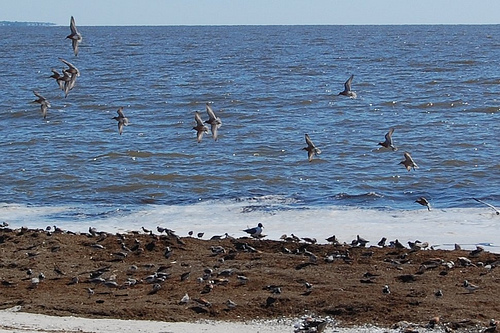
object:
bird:
[396, 151, 419, 172]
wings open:
[417, 196, 429, 204]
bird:
[376, 127, 398, 152]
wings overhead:
[384, 128, 395, 145]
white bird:
[140, 226, 150, 233]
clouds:
[0, 0, 500, 27]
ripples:
[0, 150, 292, 194]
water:
[1, 23, 500, 255]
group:
[25, 17, 432, 213]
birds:
[26, 15, 419, 172]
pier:
[0, 21, 58, 27]